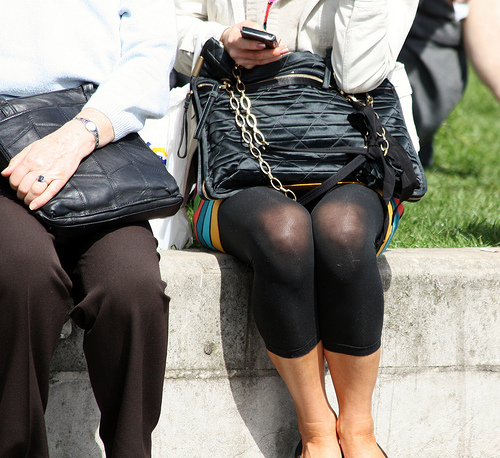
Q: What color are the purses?
A: Black.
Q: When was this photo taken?
A: During the daytime.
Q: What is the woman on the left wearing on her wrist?
A: A watch.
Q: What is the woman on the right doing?
A: Texting.